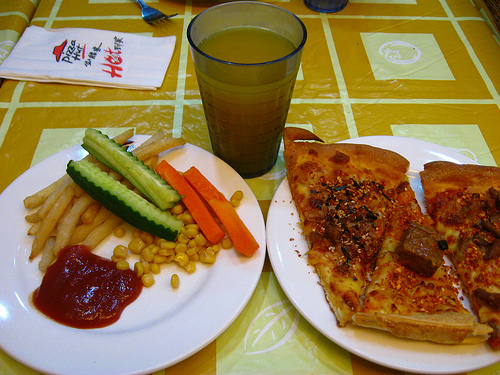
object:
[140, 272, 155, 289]
corn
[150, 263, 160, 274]
corn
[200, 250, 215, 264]
corn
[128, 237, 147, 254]
corn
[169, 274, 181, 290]
corn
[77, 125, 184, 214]
zucchini sticks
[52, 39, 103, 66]
logo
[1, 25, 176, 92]
napkin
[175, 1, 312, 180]
cup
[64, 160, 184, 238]
zucchini spear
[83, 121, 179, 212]
zucchini spear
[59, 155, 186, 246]
zucchini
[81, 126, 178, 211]
zucchini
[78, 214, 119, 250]
fry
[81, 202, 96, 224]
fry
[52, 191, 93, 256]
fry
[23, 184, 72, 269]
fry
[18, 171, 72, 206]
fry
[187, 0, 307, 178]
glass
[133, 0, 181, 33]
fork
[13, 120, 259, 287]
food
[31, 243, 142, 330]
ketchup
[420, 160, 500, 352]
pizza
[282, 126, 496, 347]
pizza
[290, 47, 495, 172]
tablecloth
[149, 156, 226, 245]
carrots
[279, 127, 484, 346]
food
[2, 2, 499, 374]
table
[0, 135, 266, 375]
plate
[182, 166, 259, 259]
carrot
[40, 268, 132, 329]
big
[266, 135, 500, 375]
plate